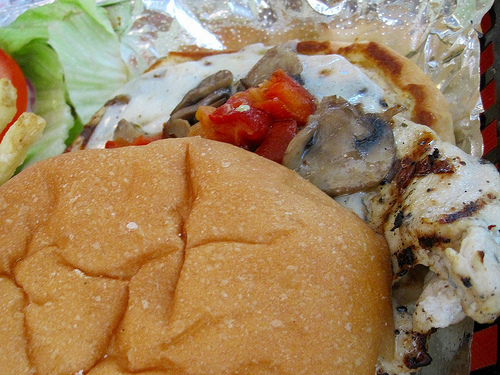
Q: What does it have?
A: Buns.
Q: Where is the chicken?
A: Inside the buns.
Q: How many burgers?
A: 1.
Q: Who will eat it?
A: A person.